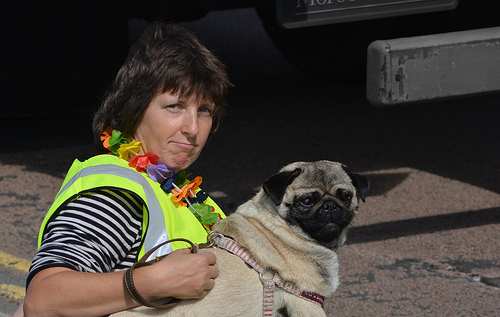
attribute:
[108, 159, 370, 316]
pug — brown, small, tan, black, looking, light brown, fat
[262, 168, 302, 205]
ear — black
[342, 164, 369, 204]
ear — black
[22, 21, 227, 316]
woman — sitting, looking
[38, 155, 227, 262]
vest — bright, yellow, silver, reflecting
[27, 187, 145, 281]
shirt — stripped, black, white, striped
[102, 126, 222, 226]
necklace — orange, green, yellow, red, purple, blue, flowered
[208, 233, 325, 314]
harness — red, white, pink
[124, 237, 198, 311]
leash — brown, yellow, leather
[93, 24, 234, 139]
hair — dark, brown, black, mullet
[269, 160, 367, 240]
head — black, tan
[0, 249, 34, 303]
lines — painted, yellow, chipped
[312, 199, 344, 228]
snout — black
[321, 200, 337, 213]
nose — black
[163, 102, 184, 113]
eye — blue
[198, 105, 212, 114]
eye — blue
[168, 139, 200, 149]
mouth — closed